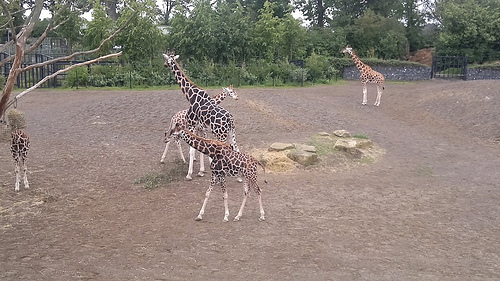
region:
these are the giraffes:
[152, 47, 257, 229]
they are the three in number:
[150, 42, 255, 242]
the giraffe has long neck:
[153, 50, 194, 97]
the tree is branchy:
[1, 15, 77, 90]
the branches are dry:
[0, 10, 59, 90]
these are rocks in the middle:
[267, 140, 317, 170]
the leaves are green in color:
[214, 9, 285, 46]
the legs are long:
[361, 85, 387, 105]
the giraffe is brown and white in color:
[194, 98, 214, 115]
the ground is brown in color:
[60, 187, 161, 279]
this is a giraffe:
[175, 120, 298, 227]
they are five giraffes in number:
[10, 42, 432, 200]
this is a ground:
[309, 185, 464, 235]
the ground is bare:
[345, 190, 434, 279]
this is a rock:
[342, 135, 369, 154]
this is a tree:
[206, 12, 251, 77]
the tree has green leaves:
[202, 32, 214, 47]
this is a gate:
[433, 59, 465, 73]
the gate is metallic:
[431, 59, 458, 74]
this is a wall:
[391, 67, 415, 80]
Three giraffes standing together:
[123, 42, 296, 237]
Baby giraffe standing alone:
[1, 113, 46, 197]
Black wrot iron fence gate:
[411, 48, 475, 87]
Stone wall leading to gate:
[341, 61, 443, 86]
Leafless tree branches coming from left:
[7, 13, 124, 233]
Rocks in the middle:
[249, 121, 383, 191]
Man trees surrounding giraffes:
[13, 5, 492, 93]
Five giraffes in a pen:
[11, 29, 445, 209]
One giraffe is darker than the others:
[159, 43, 245, 197]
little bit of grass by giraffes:
[139, 144, 196, 207]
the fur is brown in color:
[191, 104, 225, 130]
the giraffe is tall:
[163, 120, 266, 222]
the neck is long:
[186, 134, 213, 159]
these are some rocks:
[273, 140, 317, 160]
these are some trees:
[201, 0, 296, 80]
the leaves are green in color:
[206, 20, 246, 42]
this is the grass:
[151, 83, 169, 88]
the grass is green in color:
[145, 84, 168, 89]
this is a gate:
[428, 50, 470, 80]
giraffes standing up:
[152, 36, 274, 241]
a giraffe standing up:
[328, 25, 423, 157]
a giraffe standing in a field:
[124, 32, 278, 239]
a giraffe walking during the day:
[133, 22, 310, 248]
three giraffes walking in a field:
[128, 42, 331, 257]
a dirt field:
[307, 185, 447, 278]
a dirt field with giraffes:
[110, 26, 372, 240]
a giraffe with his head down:
[139, 107, 294, 230]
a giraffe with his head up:
[153, 39, 253, 153]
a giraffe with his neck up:
[135, 46, 261, 159]